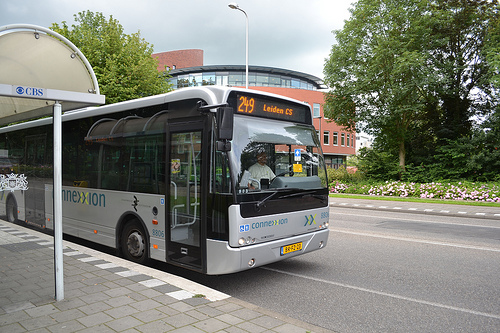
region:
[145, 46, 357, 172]
red brick building behind bus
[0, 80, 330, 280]
black and silver bus at curb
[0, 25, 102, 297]
bus shelter on sidewalk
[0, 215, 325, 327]
white and gray sidewalk next to street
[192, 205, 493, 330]
black paved street under bus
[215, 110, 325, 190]
large glass windshield on bus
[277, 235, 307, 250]
yellow license plate on bus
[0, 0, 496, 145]
dark gray cloudy sky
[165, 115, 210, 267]
glass door on bus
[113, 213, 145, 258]
black tire on bus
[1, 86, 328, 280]
city bus at bus stop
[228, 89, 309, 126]
digital bus read out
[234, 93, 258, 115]
number 249 on bus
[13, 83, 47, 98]
blue cbs on awning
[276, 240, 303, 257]
yellow license plate on bus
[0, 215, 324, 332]
sidewalk is made of bricks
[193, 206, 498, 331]
street is paved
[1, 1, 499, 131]
street is cloudy and blue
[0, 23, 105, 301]
bus stop awning is white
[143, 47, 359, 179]
large building behind bus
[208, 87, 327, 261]
front of the bus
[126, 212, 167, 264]
front tyre of the bus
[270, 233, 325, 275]
number plate of the bus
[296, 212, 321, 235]
a small indicator on bus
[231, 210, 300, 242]
name of the bus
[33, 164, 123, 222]
name of the bus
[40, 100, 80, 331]
a long iron poll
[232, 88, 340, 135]
destination display on the bus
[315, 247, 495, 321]
a white line on road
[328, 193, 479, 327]
a neat clean road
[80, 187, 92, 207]
blue and yellow x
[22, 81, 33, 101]
the blue letter c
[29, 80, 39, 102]
the blue letter b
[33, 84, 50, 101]
the blue letter s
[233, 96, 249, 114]
the orange number 2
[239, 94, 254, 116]
the orange number 4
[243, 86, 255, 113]
the orange number 9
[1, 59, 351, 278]
this is a bus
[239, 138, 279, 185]
this is a bus driver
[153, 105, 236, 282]
this is a door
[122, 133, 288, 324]
a bus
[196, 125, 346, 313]
a bus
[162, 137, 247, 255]
a bus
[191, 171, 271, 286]
a bus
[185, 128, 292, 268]
a bus